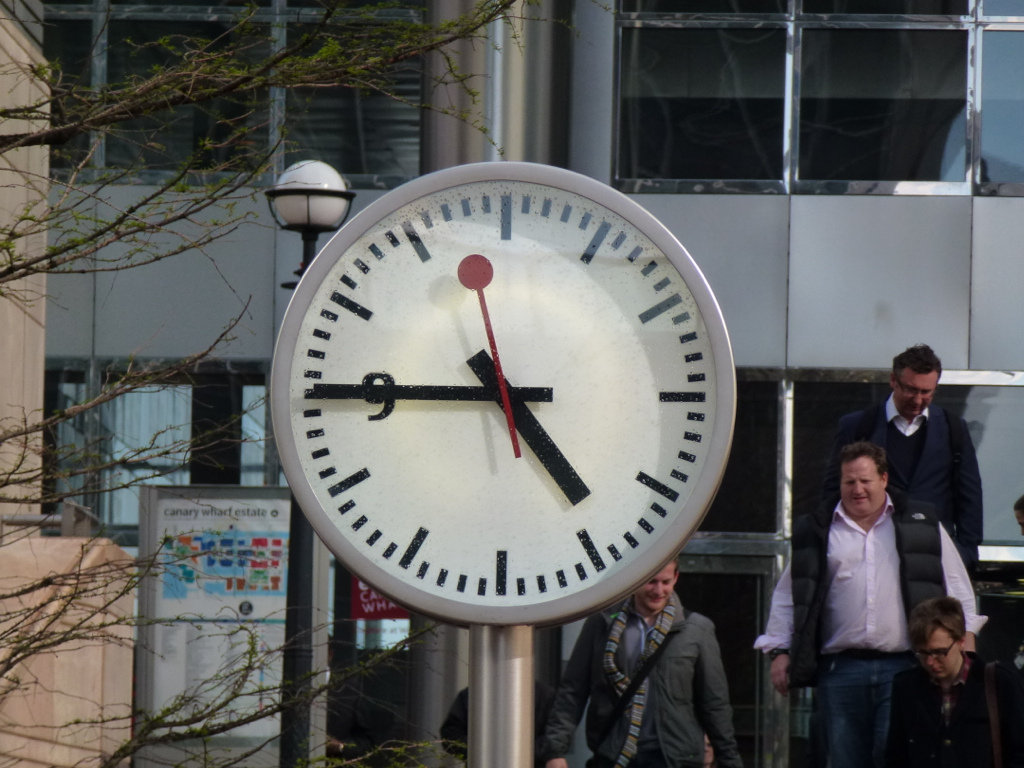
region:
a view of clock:
[312, 181, 831, 546]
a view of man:
[776, 458, 1011, 740]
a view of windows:
[62, 203, 287, 511]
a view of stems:
[108, 509, 296, 757]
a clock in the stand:
[262, 129, 926, 766]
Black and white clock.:
[288, 164, 754, 627]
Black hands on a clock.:
[307, 347, 593, 529]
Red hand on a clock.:
[442, 235, 570, 480]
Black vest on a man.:
[778, 496, 988, 677]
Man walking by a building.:
[783, 443, 932, 729]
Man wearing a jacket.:
[853, 339, 987, 551]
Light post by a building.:
[252, 145, 366, 765]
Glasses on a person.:
[910, 635, 962, 668]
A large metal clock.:
[266, 161, 738, 766]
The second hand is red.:
[454, 252, 521, 459]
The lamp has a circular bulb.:
[263, 158, 358, 766]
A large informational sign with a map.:
[131, 483, 329, 766]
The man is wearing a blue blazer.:
[819, 342, 984, 577]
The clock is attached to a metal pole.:
[266, 160, 738, 767]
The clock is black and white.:
[255, 193, 750, 649]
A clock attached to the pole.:
[278, 146, 708, 605]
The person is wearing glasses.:
[913, 642, 961, 663]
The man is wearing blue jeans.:
[795, 661, 917, 761]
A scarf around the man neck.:
[612, 610, 690, 735]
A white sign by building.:
[122, 468, 320, 754]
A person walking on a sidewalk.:
[543, 551, 740, 766]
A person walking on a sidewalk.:
[751, 440, 987, 766]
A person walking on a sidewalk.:
[824, 343, 983, 593]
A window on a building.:
[94, 362, 271, 530]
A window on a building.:
[101, 10, 278, 179]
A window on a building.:
[281, 13, 425, 176]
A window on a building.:
[616, 23, 787, 180]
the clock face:
[282, 176, 729, 616]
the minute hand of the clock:
[301, 370, 567, 418]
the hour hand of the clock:
[469, 338, 602, 513]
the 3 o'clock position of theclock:
[643, 370, 723, 419]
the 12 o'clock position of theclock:
[482, 162, 525, 249]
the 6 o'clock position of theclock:
[482, 524, 530, 604]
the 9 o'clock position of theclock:
[310, 366, 410, 428]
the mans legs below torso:
[808, 657, 919, 766]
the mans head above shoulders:
[826, 437, 896, 517]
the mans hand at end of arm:
[750, 641, 807, 693]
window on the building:
[877, 382, 976, 501]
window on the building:
[646, 508, 733, 689]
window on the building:
[99, 309, 233, 563]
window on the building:
[807, 16, 932, 176]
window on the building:
[582, 31, 722, 177]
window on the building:
[971, 13, 1020, 118]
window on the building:
[286, 13, 423, 200]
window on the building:
[105, 16, 280, 258]